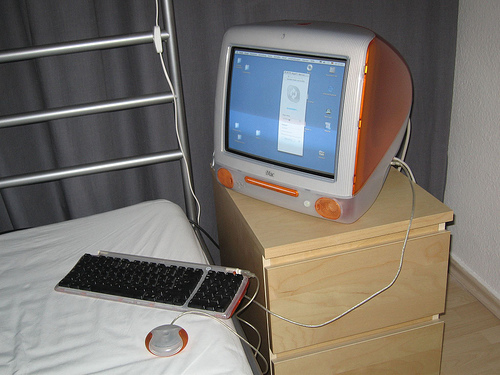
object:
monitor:
[224, 44, 348, 180]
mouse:
[145, 324, 188, 357]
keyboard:
[55, 250, 250, 320]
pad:
[189, 270, 243, 312]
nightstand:
[214, 166, 455, 375]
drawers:
[262, 227, 452, 375]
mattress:
[1, 198, 254, 374]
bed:
[0, 194, 262, 375]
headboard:
[0, 0, 201, 230]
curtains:
[0, 0, 455, 256]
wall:
[443, 0, 500, 200]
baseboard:
[449, 253, 498, 319]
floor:
[440, 315, 499, 375]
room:
[0, 0, 499, 374]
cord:
[244, 116, 416, 328]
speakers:
[244, 176, 299, 197]